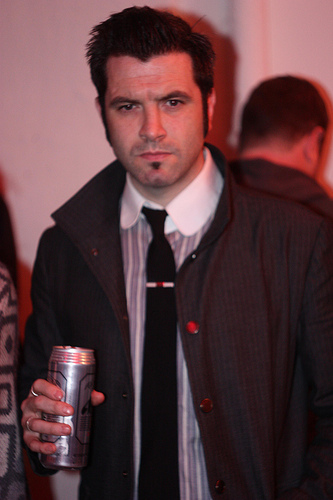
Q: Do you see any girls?
A: No, there are no girls.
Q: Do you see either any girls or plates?
A: No, there are no girls or plates.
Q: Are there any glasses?
A: No, there are no glasses.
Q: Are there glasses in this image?
A: No, there are no glasses.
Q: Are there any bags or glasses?
A: No, there are no glasses or bags.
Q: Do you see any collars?
A: Yes, there is a collar.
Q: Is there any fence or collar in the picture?
A: Yes, there is a collar.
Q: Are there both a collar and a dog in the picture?
A: No, there is a collar but no dogs.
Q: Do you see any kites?
A: No, there are no kites.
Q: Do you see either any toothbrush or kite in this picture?
A: No, there are no kites or toothbrushes.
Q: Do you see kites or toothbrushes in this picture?
A: No, there are no kites or toothbrushes.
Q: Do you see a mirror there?
A: No, there are no mirrors.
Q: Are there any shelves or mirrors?
A: No, there are no mirrors or shelves.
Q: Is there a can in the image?
A: Yes, there is a can.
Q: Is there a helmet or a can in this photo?
A: Yes, there is a can.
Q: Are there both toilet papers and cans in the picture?
A: No, there is a can but no toilet papers.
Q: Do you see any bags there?
A: No, there are no bags.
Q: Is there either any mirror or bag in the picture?
A: No, there are no bags or mirrors.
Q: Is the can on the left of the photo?
A: Yes, the can is on the left of the image.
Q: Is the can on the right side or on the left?
A: The can is on the left of the image.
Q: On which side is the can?
A: The can is on the left of the image.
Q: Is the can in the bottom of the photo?
A: Yes, the can is in the bottom of the image.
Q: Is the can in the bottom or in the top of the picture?
A: The can is in the bottom of the image.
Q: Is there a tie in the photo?
A: Yes, there is a tie.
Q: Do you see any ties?
A: Yes, there is a tie.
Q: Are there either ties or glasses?
A: Yes, there is a tie.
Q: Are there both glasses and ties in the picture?
A: No, there is a tie but no glasses.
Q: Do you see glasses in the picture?
A: No, there are no glasses.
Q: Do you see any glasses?
A: No, there are no glasses.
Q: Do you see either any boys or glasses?
A: No, there are no glasses or boys.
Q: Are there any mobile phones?
A: No, there are no mobile phones.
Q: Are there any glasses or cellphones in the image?
A: No, there are no cellphones or glasses.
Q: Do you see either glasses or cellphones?
A: No, there are no cellphones or glasses.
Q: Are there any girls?
A: No, there are no girls.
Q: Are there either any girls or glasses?
A: No, there are no girls or glasses.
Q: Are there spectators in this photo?
A: No, there are no spectators.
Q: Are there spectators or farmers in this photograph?
A: No, there are no spectators or farmers.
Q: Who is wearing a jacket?
A: The guy is wearing a jacket.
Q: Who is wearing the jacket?
A: The guy is wearing a jacket.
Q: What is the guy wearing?
A: The guy is wearing a jacket.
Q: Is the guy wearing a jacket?
A: Yes, the guy is wearing a jacket.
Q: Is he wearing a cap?
A: No, the guy is wearing a jacket.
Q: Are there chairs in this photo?
A: No, there are no chairs.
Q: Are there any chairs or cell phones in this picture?
A: No, there are no chairs or cell phones.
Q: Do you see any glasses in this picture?
A: No, there are no glasses.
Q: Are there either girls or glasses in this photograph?
A: No, there are no glasses or girls.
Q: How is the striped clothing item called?
A: The clothing item is a shirt.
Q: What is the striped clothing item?
A: The clothing item is a shirt.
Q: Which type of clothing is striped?
A: The clothing is a shirt.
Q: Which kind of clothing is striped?
A: The clothing is a shirt.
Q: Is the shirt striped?
A: Yes, the shirt is striped.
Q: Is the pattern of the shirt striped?
A: Yes, the shirt is striped.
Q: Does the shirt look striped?
A: Yes, the shirt is striped.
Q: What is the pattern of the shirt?
A: The shirt is striped.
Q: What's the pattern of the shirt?
A: The shirt is striped.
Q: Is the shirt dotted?
A: No, the shirt is striped.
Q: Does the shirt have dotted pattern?
A: No, the shirt is striped.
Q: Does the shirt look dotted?
A: No, the shirt is striped.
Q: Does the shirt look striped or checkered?
A: The shirt is striped.